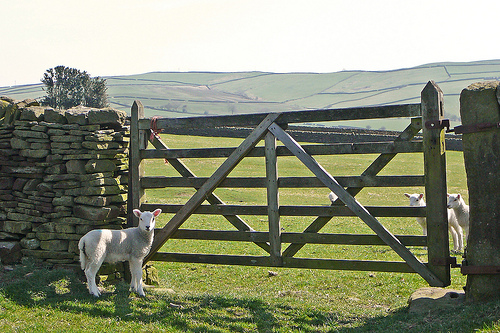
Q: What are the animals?
A: Sheep.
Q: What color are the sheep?
A: White.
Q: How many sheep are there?
A: Three.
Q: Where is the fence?
A: Beside sheep.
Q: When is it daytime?
A: Now.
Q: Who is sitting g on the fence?
A: No one.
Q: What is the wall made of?
A: Rock.